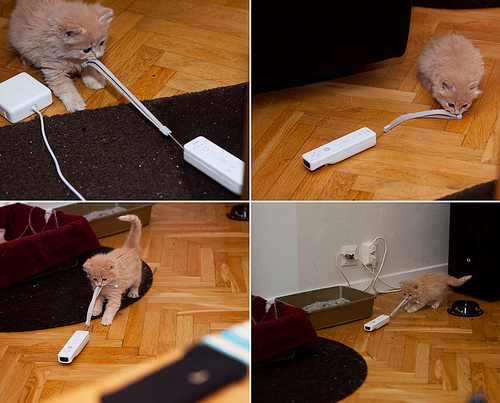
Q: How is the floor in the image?
A: Wood.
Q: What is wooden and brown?
A: The floor.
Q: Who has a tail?
A: The cat.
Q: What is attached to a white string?
A: Game controller.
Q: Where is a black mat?
A: On the floor.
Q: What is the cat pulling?
A: A game controller.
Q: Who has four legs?
A: A kitten.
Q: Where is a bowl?
A: On the floor.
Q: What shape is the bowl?
A: Round.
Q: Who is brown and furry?
A: The cat.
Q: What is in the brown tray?
A: Cat litter.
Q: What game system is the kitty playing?
A: Nintendo Wii.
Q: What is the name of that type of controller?
A: Wiimote.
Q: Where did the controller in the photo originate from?
A: Japan.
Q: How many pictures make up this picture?
A: 4.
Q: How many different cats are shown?
A: 1.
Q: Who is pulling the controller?
A: Kitten.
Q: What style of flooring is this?
A: Parquet flooring.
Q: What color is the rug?
A: Black.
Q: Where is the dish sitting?
A: Floor.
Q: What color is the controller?
A: White.